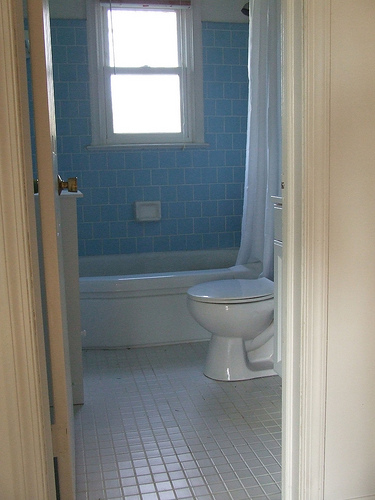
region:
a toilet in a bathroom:
[2, 5, 371, 495]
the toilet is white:
[181, 267, 278, 387]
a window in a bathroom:
[83, 2, 211, 155]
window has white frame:
[80, 0, 211, 153]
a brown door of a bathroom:
[18, 5, 102, 496]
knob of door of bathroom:
[50, 163, 83, 202]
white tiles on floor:
[75, 343, 283, 498]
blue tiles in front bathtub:
[47, 14, 260, 288]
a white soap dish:
[126, 193, 166, 228]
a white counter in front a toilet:
[63, 181, 277, 419]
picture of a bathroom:
[6, 16, 368, 487]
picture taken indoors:
[28, 49, 324, 451]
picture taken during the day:
[118, 29, 183, 129]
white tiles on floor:
[109, 367, 188, 480]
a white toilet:
[167, 236, 281, 405]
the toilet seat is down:
[183, 258, 269, 328]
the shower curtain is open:
[227, 10, 261, 274]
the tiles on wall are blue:
[183, 166, 217, 227]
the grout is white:
[174, 147, 230, 267]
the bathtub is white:
[92, 277, 158, 329]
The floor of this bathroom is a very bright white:
[185, 431, 217, 465]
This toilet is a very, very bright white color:
[199, 277, 285, 395]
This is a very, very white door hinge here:
[44, 418, 72, 469]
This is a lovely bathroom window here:
[85, 11, 220, 158]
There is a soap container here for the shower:
[135, 188, 172, 231]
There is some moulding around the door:
[295, 297, 345, 464]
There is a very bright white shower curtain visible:
[240, 30, 296, 210]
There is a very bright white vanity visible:
[273, 224, 283, 369]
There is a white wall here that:
[351, 335, 373, 418]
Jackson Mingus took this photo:
[45, 32, 324, 490]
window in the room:
[88, 4, 213, 134]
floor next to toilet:
[123, 382, 195, 459]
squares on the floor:
[114, 370, 192, 454]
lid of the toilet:
[187, 275, 265, 311]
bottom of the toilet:
[202, 330, 266, 386]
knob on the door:
[49, 167, 89, 214]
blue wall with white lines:
[182, 154, 227, 204]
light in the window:
[124, 20, 187, 113]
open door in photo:
[8, 36, 90, 235]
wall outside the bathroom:
[314, 61, 370, 238]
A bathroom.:
[1, 0, 368, 497]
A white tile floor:
[72, 337, 284, 494]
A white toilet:
[180, 264, 278, 386]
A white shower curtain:
[236, 1, 276, 258]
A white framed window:
[82, 1, 202, 143]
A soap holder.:
[131, 198, 157, 219]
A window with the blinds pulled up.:
[85, 2, 205, 147]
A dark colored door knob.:
[35, 171, 78, 194]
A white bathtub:
[72, 243, 246, 349]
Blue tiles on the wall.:
[22, 19, 247, 254]